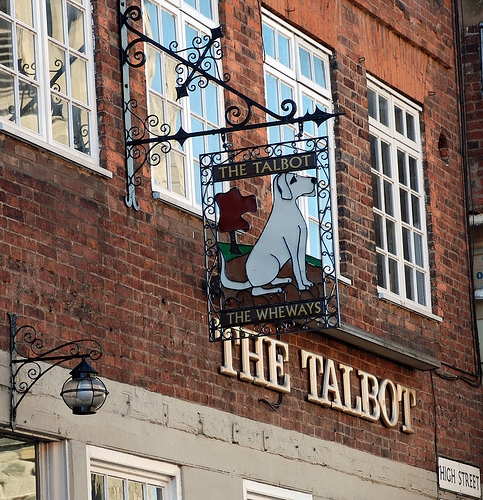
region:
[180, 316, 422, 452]
the sign is gold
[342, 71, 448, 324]
the window pane is white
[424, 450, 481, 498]
the sign is black and white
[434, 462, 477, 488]
the letters are black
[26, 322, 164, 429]
the light is off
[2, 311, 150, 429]
the light is attached to the wall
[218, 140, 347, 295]
a dog on the sign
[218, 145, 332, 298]
the dog is white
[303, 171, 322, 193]
the nose is black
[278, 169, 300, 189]
the eye is black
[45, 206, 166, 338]
a red, bricked wall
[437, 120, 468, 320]
a red, bricked wall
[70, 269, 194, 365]
a red, bricked wall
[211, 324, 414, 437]
white lettering attached to brick wall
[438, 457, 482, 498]
white sign with black lettering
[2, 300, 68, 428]
bracket attaching light to wall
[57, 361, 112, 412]
black street lamp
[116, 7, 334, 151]
bracket attatching business sign to brick wall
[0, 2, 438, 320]
four windows in brick wall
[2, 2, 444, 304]
white frams of four windows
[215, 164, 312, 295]
white dog figure on sign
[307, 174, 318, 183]
black nose of white dog figure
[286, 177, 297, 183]
black eye of white dog figure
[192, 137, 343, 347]
a multi-colored sign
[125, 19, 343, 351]
a sign hanging on a wall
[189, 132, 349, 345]
a sign with a white dog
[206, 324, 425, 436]
lettering on a brick wall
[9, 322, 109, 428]
a lamp on a wall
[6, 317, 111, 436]
a black metal lamp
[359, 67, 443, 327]
a white window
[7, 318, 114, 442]
a light fixture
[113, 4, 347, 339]
a fancy sign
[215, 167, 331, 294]
a white dog facing right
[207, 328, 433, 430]
gold lettering on brick building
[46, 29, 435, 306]
large red brick building with white letters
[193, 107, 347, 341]
white dog on an iron sign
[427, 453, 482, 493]
street sign for high street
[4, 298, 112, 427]
light hanging from a decorative iron hanger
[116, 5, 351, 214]
decorative iron sign hanger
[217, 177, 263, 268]
brown tree on the sign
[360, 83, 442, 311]
window with a white frame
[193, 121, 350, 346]
sign for The Talbot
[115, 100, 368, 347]
sign attached to building of business